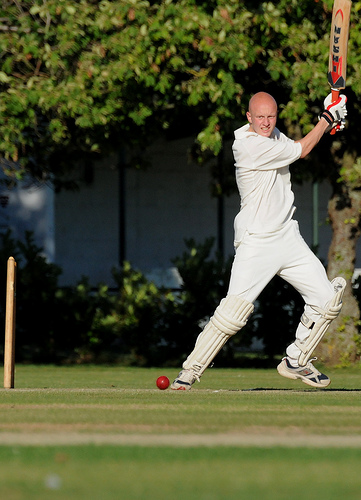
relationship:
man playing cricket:
[170, 91, 347, 391] [156, 0, 352, 392]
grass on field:
[0, 363, 360, 499] [0, 1, 360, 499]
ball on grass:
[156, 376, 171, 391] [0, 363, 360, 499]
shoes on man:
[168, 357, 332, 391] [170, 91, 347, 391]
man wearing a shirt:
[170, 91, 347, 391] [233, 122, 302, 245]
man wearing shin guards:
[170, 91, 347, 391] [182, 276, 347, 375]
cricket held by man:
[325, 0, 353, 140] [170, 91, 347, 391]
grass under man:
[0, 363, 360, 499] [170, 91, 347, 391]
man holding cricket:
[170, 91, 347, 391] [325, 0, 353, 140]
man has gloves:
[170, 91, 347, 391] [318, 92, 347, 134]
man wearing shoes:
[170, 91, 347, 391] [168, 357, 332, 391]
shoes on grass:
[168, 357, 332, 391] [0, 363, 360, 499]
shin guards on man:
[182, 276, 347, 375] [170, 91, 347, 391]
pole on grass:
[4, 254, 16, 388] [0, 363, 360, 499]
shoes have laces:
[168, 357, 332, 391] [178, 355, 322, 385]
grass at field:
[0, 363, 360, 499] [0, 1, 360, 499]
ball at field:
[156, 376, 171, 391] [0, 1, 360, 499]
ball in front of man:
[156, 376, 171, 391] [170, 91, 347, 391]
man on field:
[170, 91, 347, 391] [0, 1, 360, 499]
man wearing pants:
[170, 91, 347, 391] [182, 219, 337, 372]